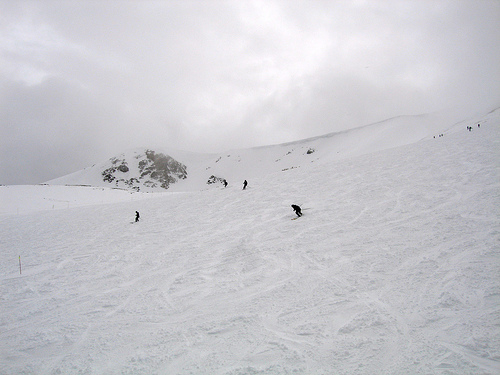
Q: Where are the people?
A: On the snow.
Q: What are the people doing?
A: Skiing.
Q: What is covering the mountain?
A: Snow.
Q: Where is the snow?
A: On the ground.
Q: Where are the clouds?
A: In the sky.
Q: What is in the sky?
A: Clouds.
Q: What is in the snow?
A: Tracks.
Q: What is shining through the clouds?
A: Sunlight.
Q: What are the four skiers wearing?
A: Black.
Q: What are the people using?
A: Skis.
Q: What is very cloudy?
A: The sky.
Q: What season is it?
A: Winter.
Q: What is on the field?
A: Snow.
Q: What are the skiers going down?
A: A hill.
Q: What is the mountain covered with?
A: Snow.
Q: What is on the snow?
A: Tracks.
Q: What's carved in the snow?
A: Ski paths.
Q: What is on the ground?
A: Snow.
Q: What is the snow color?
A: White.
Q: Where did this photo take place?
A: On a ski hill.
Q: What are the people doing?
A: Skiing.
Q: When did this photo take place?
A: During the day.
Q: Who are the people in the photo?
A: Skiiers.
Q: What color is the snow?
A: White.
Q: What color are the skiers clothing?
A: Black.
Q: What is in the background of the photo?
A: A mountain.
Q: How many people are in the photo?
A: Four.